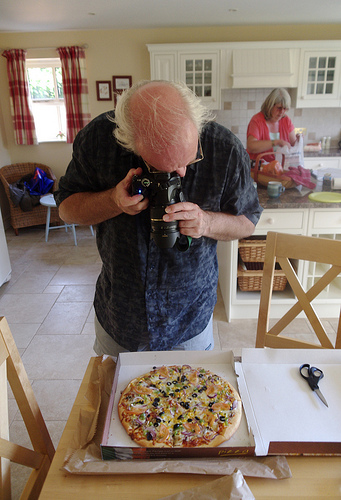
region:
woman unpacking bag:
[250, 83, 324, 202]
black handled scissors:
[291, 356, 339, 409]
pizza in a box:
[106, 340, 317, 493]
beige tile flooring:
[28, 270, 102, 389]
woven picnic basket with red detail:
[249, 143, 311, 211]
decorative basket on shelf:
[238, 233, 299, 302]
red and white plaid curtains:
[2, 39, 100, 162]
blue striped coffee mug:
[264, 172, 291, 204]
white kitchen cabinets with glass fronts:
[153, 33, 338, 99]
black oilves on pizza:
[155, 381, 192, 425]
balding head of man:
[118, 82, 226, 156]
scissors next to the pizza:
[287, 371, 326, 420]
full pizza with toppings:
[121, 370, 234, 459]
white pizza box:
[237, 387, 296, 466]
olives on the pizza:
[174, 390, 196, 413]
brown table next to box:
[290, 459, 336, 492]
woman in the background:
[249, 88, 300, 154]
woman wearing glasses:
[263, 94, 298, 125]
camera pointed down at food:
[135, 169, 209, 244]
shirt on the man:
[67, 106, 245, 317]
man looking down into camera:
[55, 86, 272, 288]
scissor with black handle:
[294, 358, 331, 411]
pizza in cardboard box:
[113, 354, 247, 451]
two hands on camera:
[118, 167, 204, 252]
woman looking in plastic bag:
[250, 90, 311, 174]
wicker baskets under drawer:
[233, 227, 306, 291]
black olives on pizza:
[168, 386, 199, 409]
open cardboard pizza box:
[91, 341, 312, 462]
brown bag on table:
[69, 454, 230, 483]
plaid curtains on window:
[58, 46, 100, 140]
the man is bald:
[84, 79, 226, 230]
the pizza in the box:
[105, 356, 275, 466]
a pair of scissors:
[279, 359, 335, 409]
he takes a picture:
[87, 119, 239, 269]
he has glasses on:
[84, 110, 254, 244]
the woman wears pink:
[234, 72, 332, 194]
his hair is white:
[80, 56, 245, 256]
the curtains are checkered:
[49, 37, 108, 167]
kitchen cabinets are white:
[136, 35, 340, 125]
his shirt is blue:
[38, 104, 302, 358]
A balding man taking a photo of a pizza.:
[55, 77, 262, 352]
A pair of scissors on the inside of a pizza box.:
[299, 361, 329, 409]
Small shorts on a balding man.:
[91, 308, 216, 358]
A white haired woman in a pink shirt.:
[245, 83, 305, 185]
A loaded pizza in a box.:
[118, 365, 243, 446]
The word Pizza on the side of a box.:
[216, 445, 250, 455]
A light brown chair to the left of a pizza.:
[1, 315, 57, 498]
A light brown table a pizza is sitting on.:
[37, 355, 340, 498]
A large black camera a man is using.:
[128, 169, 189, 253]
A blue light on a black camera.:
[136, 189, 142, 193]